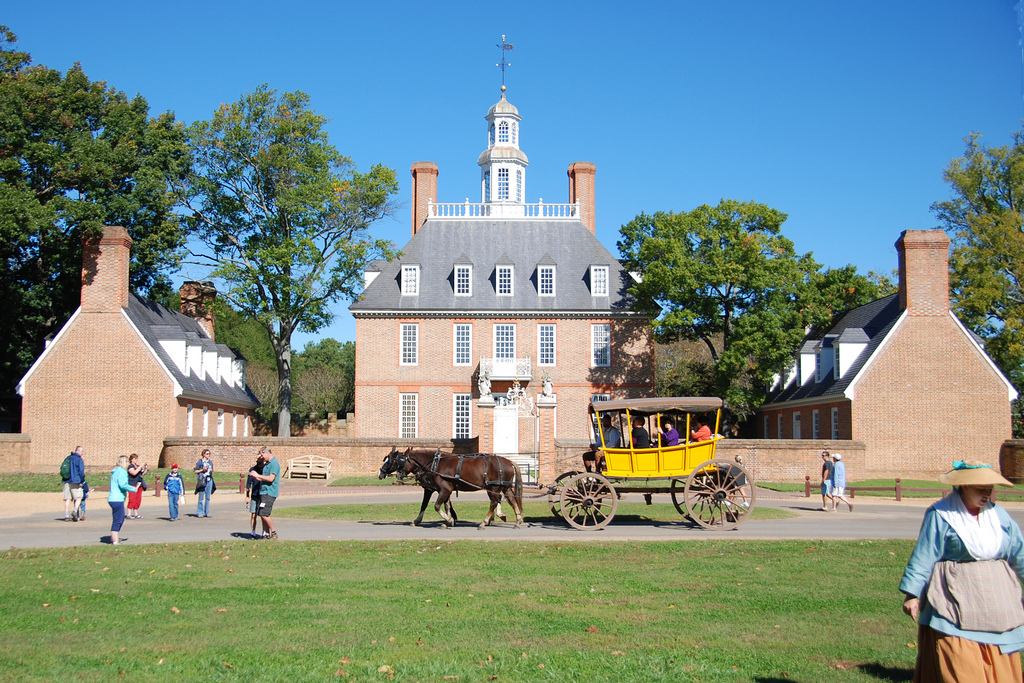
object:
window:
[537, 265, 556, 297]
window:
[399, 322, 419, 366]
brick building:
[343, 26, 661, 488]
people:
[107, 455, 142, 547]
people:
[813, 451, 857, 513]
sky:
[0, 0, 1024, 358]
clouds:
[607, 131, 700, 197]